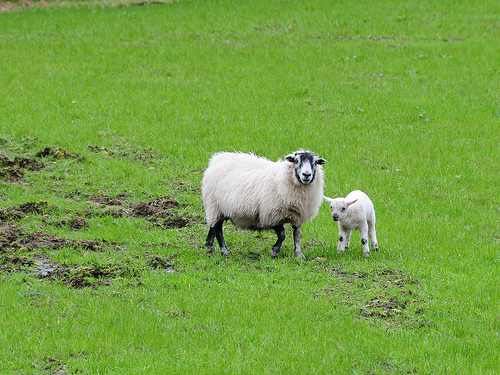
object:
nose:
[332, 214, 338, 219]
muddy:
[2, 143, 193, 295]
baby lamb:
[323, 190, 379, 258]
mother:
[200, 147, 328, 259]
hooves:
[270, 244, 281, 259]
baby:
[323, 190, 380, 258]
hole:
[0, 146, 205, 375]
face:
[294, 153, 318, 184]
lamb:
[200, 147, 328, 261]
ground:
[1, 0, 498, 373]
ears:
[285, 154, 293, 163]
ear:
[347, 199, 358, 207]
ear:
[323, 195, 334, 204]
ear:
[316, 158, 327, 166]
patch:
[361, 238, 368, 246]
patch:
[338, 235, 343, 242]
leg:
[337, 229, 349, 254]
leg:
[359, 226, 370, 258]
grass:
[0, 0, 500, 375]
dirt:
[2, 134, 439, 333]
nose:
[302, 173, 312, 179]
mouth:
[302, 179, 310, 182]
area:
[0, 0, 500, 375]